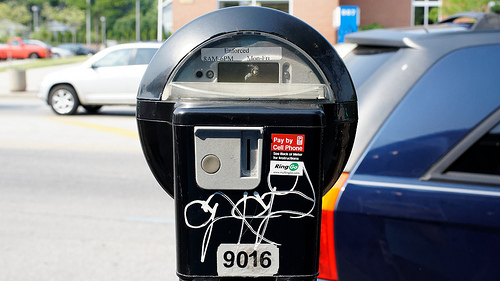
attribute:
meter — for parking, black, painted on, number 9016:
[134, 5, 359, 280]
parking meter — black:
[135, 4, 359, 280]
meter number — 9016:
[222, 247, 273, 272]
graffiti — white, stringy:
[180, 160, 318, 262]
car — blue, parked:
[318, 26, 500, 279]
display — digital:
[214, 59, 282, 87]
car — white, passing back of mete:
[26, 40, 165, 117]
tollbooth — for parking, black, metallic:
[135, 3, 360, 279]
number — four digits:
[221, 248, 272, 273]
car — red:
[2, 31, 52, 66]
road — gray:
[0, 102, 179, 280]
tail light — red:
[318, 171, 353, 280]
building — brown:
[171, 3, 498, 46]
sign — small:
[267, 131, 306, 178]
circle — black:
[134, 5, 359, 198]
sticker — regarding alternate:
[268, 130, 305, 176]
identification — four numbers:
[214, 240, 282, 278]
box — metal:
[171, 107, 328, 280]